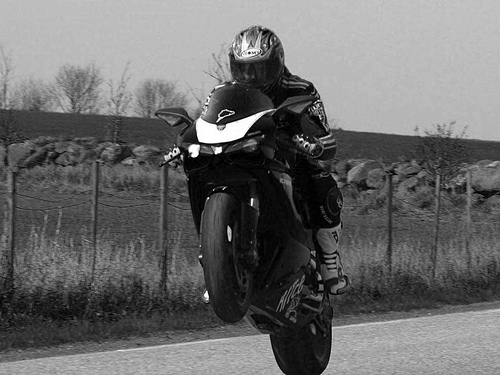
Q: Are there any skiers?
A: No, there are no skiers.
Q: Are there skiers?
A: No, there are no skiers.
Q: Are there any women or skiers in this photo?
A: No, there are no skiers or women.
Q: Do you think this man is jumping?
A: Yes, the man is jumping.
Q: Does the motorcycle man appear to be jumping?
A: Yes, the man is jumping.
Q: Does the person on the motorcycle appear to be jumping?
A: Yes, the man is jumping.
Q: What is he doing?
A: The man is jumping.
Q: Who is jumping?
A: The man is jumping.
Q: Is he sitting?
A: No, the man is jumping.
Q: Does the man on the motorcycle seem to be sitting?
A: No, the man is jumping.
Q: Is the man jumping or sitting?
A: The man is jumping.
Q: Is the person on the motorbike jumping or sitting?
A: The man is jumping.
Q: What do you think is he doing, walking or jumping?
A: The man is jumping.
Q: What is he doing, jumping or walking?
A: The man is jumping.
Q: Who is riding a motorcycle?
A: The man is riding a motorcycle.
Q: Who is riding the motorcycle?
A: The man is riding a motorcycle.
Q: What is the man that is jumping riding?
A: The man is riding a motorcycle.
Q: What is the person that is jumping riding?
A: The man is riding a motorcycle.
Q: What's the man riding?
A: The man is riding a motorcycle.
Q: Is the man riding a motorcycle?
A: Yes, the man is riding a motorcycle.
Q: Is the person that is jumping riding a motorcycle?
A: Yes, the man is riding a motorcycle.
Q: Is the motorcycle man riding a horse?
A: No, the man is riding a motorcycle.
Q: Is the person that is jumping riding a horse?
A: No, the man is riding a motorcycle.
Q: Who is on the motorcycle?
A: The man is on the motorbike.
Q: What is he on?
A: The man is on the motorcycle.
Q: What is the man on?
A: The man is on the motorcycle.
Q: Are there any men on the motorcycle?
A: Yes, there is a man on the motorcycle.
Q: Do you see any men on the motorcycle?
A: Yes, there is a man on the motorcycle.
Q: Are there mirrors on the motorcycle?
A: No, there is a man on the motorcycle.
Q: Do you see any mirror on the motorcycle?
A: No, there is a man on the motorcycle.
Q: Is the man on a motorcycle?
A: Yes, the man is on a motorcycle.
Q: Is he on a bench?
A: No, the man is on a motorcycle.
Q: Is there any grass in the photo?
A: Yes, there is grass.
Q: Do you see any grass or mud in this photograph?
A: Yes, there is grass.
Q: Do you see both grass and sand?
A: No, there is grass but no sand.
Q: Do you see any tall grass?
A: Yes, there is tall grass.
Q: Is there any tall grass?
A: Yes, there is tall grass.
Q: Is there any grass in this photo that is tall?
A: Yes, there is grass that is tall.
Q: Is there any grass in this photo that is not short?
A: Yes, there is tall grass.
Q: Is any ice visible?
A: No, there is no ice.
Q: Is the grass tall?
A: Yes, the grass is tall.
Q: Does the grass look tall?
A: Yes, the grass is tall.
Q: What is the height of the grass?
A: The grass is tall.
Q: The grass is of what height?
A: The grass is tall.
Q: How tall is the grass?
A: The grass is tall.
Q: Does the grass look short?
A: No, the grass is tall.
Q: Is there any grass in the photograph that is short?
A: No, there is grass but it is tall.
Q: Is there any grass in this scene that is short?
A: No, there is grass but it is tall.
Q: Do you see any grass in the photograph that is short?
A: No, there is grass but it is tall.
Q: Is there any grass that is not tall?
A: No, there is grass but it is tall.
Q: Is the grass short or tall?
A: The grass is tall.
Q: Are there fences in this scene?
A: Yes, there is a fence.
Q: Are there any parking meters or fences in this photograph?
A: Yes, there is a fence.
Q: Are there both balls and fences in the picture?
A: No, there is a fence but no balls.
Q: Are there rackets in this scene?
A: No, there are no rackets.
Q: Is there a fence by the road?
A: Yes, there is a fence by the road.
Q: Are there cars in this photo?
A: No, there are no cars.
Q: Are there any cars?
A: No, there are no cars.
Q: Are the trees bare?
A: Yes, the trees are bare.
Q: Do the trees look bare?
A: Yes, the trees are bare.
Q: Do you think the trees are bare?
A: Yes, the trees are bare.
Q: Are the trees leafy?
A: No, the trees are bare.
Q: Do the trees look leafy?
A: No, the trees are bare.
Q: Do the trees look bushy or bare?
A: The trees are bare.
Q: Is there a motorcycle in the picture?
A: Yes, there is a motorcycle.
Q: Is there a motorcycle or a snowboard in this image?
A: Yes, there is a motorcycle.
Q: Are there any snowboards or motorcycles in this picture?
A: Yes, there is a motorcycle.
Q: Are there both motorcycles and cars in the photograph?
A: No, there is a motorcycle but no cars.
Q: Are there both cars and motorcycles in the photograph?
A: No, there is a motorcycle but no cars.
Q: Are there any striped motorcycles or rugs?
A: Yes, there is a striped motorcycle.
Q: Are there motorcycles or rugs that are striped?
A: Yes, the motorcycle is striped.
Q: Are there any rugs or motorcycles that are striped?
A: Yes, the motorcycle is striped.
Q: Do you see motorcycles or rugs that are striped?
A: Yes, the motorcycle is striped.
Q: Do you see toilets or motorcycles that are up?
A: Yes, the motorcycle is up.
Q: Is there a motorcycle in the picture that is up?
A: Yes, there is a motorcycle that is up.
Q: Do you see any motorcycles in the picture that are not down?
A: Yes, there is a motorcycle that is up .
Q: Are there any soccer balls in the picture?
A: No, there are no soccer balls.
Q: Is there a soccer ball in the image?
A: No, there are no soccer balls.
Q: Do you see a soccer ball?
A: No, there are no soccer balls.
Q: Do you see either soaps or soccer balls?
A: No, there are no soccer balls or soaps.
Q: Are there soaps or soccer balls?
A: No, there are no soccer balls or soaps.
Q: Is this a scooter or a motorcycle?
A: This is a motorcycle.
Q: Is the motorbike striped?
A: Yes, the motorbike is striped.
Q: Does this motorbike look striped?
A: Yes, the motorbike is striped.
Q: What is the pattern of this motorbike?
A: The motorbike is striped.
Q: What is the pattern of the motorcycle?
A: The motorbike is striped.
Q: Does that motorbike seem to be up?
A: Yes, the motorbike is up.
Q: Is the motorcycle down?
A: No, the motorcycle is up.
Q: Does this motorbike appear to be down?
A: No, the motorbike is up.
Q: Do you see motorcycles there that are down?
A: No, there is a motorcycle but it is up.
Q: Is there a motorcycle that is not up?
A: No, there is a motorcycle but it is up.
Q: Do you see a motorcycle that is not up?
A: No, there is a motorcycle but it is up.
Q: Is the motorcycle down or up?
A: The motorcycle is up.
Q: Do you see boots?
A: Yes, there are boots.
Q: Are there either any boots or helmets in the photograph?
A: Yes, there are boots.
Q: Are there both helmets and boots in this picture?
A: Yes, there are both boots and a helmet.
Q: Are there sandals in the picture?
A: No, there are no sandals.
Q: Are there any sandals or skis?
A: No, there are no sandals or skis.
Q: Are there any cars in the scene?
A: No, there are no cars.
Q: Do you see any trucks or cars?
A: No, there are no cars or trucks.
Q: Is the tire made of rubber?
A: Yes, the tire is made of rubber.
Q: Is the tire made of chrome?
A: No, the tire is made of rubber.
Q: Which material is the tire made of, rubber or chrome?
A: The tire is made of rubber.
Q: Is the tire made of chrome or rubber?
A: The tire is made of rubber.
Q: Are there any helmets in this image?
A: Yes, there is a helmet.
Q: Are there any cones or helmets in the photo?
A: Yes, there is a helmet.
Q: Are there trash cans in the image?
A: No, there are no trash cans.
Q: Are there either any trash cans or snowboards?
A: No, there are no trash cans or snowboards.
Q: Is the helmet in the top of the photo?
A: Yes, the helmet is in the top of the image.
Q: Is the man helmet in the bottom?
A: No, the helmet is in the top of the image.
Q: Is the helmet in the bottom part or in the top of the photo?
A: The helmet is in the top of the image.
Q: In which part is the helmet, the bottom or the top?
A: The helmet is in the top of the image.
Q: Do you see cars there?
A: No, there are no cars.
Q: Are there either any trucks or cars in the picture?
A: No, there are no cars or trucks.